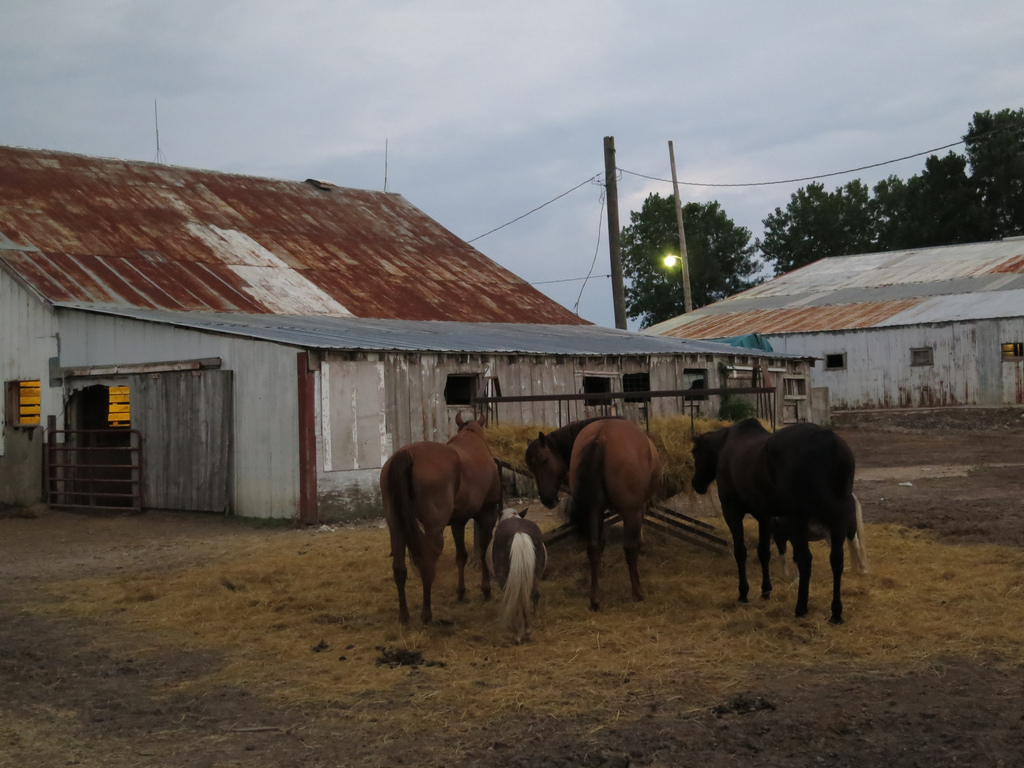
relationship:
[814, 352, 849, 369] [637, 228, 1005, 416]
window on building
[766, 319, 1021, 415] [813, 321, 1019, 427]
building side on building side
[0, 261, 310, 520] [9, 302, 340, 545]
building side on building side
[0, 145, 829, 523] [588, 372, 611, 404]
building has a window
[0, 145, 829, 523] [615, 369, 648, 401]
building has a window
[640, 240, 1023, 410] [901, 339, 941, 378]
building has a window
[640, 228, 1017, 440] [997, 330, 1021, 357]
building has a window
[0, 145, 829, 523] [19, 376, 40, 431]
building has a window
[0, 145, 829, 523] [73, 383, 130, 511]
building has window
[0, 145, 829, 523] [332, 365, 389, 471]
building has window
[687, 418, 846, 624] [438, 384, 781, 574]
horse stands by hay trough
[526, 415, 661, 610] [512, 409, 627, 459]
horse with mane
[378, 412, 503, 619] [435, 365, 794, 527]
horse by hay trough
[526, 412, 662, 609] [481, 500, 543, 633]
horse looks at pony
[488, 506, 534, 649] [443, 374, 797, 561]
pony stands by hay trough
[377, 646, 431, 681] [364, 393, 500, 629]
manure behind horse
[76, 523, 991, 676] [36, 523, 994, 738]
hay on ground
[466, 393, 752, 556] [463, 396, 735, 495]
hay trough full of hay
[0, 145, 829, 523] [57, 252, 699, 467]
building has window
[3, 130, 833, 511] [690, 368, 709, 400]
building has window